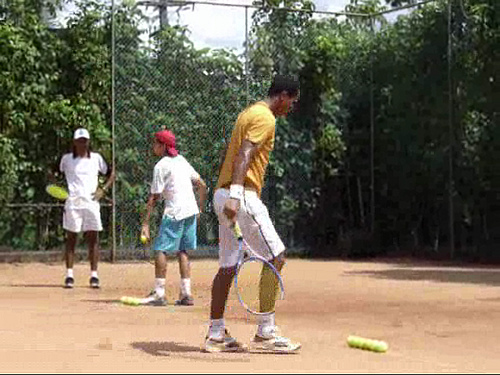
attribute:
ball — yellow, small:
[373, 337, 390, 354]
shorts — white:
[55, 207, 105, 235]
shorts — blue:
[152, 214, 220, 282]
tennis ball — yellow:
[346, 333, 388, 352]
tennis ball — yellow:
[119, 295, 141, 306]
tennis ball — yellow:
[138, 233, 148, 243]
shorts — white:
[211, 187, 288, 270]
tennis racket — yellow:
[42, 183, 70, 202]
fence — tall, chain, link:
[274, 0, 483, 253]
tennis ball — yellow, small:
[139, 233, 169, 253]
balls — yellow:
[347, 334, 390, 351]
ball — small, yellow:
[345, 335, 354, 345]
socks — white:
[206, 312, 276, 341]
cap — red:
[150, 127, 180, 158]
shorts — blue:
[153, 215, 199, 259]